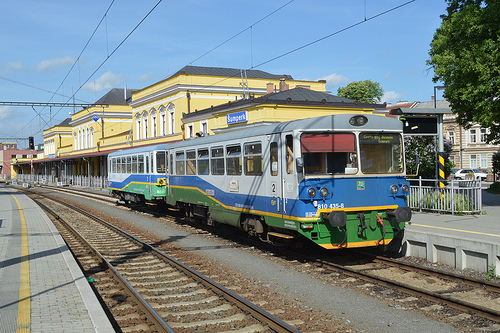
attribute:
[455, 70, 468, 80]
leaves — green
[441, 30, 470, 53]
leaves — green